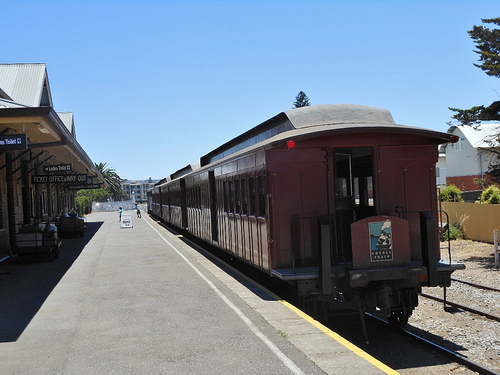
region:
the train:
[207, 140, 437, 273]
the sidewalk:
[94, 228, 198, 369]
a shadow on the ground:
[14, 261, 52, 301]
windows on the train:
[215, 187, 272, 214]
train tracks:
[424, 346, 475, 371]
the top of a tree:
[283, 88, 310, 110]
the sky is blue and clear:
[105, 35, 260, 121]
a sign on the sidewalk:
[111, 205, 142, 226]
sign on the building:
[2, 134, 23, 146]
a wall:
[457, 206, 498, 232]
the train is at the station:
[143, 105, 460, 310]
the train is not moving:
[141, 90, 456, 329]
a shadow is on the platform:
[143, 206, 293, 314]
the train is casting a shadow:
[144, 206, 321, 307]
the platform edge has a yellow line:
[147, 207, 410, 372]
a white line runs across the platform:
[130, 207, 309, 370]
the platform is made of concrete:
[11, 207, 383, 369]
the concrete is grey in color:
[1, 212, 409, 372]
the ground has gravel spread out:
[282, 233, 495, 374]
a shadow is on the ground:
[323, 292, 471, 372]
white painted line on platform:
[134, 209, 304, 373]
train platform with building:
[1, 59, 402, 373]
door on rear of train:
[333, 147, 383, 267]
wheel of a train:
[380, 302, 416, 330]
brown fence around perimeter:
[437, 196, 498, 242]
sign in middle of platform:
[115, 208, 140, 232]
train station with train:
[0, 55, 483, 372]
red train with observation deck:
[183, 102, 474, 328]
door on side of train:
[204, 170, 223, 243]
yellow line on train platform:
[147, 207, 404, 369]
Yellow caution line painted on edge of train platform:
[144, 209, 396, 374]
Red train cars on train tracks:
[146, 103, 465, 331]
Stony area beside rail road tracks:
[401, 237, 498, 373]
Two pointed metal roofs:
[1, 60, 77, 135]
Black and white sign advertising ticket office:
[28, 173, 89, 185]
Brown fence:
[439, 198, 499, 243]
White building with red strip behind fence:
[441, 122, 498, 242]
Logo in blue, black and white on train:
[368, 220, 395, 262]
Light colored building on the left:
[2, 62, 109, 268]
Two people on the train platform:
[116, 200, 143, 229]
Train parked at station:
[145, 103, 461, 320]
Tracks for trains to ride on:
[353, 278, 497, 372]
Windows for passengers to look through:
[220, 179, 260, 217]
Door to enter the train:
[330, 150, 385, 268]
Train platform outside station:
[64, 206, 389, 373]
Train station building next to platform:
[1, 65, 106, 252]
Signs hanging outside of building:
[27, 162, 106, 189]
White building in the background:
[116, 179, 151, 202]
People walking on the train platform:
[116, 203, 148, 220]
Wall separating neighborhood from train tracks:
[439, 200, 497, 244]